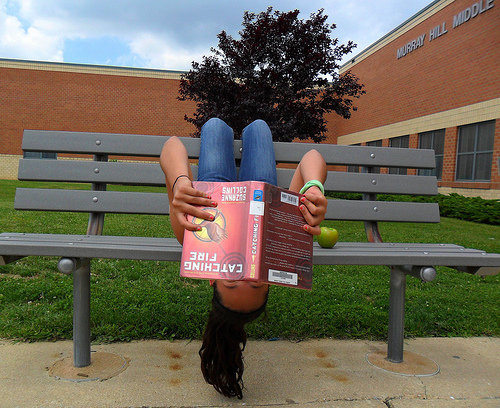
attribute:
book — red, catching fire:
[177, 179, 315, 290]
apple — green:
[318, 224, 342, 250]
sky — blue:
[3, 0, 428, 57]